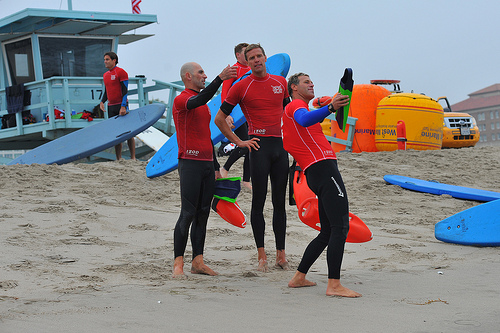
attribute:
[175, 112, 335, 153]
tops — red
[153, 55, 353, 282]
men — standing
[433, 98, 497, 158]
vehicle — yellow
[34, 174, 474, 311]
sand — dry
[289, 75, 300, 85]
hair — short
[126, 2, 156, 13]
flag — american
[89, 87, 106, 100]
number — 17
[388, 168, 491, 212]
surfboard — blue, long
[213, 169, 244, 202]
shoe — green, black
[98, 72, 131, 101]
shirt — red, nylon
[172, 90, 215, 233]
wetsuit — red, black, blue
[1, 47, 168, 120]
stand — blue, wood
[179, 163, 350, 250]
pants — black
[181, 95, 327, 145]
shirts — red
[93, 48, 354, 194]
lifeguards — five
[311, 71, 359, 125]
flipper — green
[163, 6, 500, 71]
sky — cloudy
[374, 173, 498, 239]
surfboards — blue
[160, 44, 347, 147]
surfers — posing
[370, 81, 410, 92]
roof — red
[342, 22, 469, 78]
clouds — dark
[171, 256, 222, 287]
feet — bare